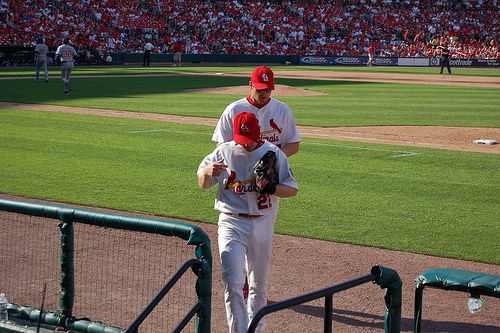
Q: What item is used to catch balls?
A: Glove.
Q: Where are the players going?
A: The dugout.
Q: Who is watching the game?
A: The spectator.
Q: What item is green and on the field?
A: Grass.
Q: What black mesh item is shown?
A: A net.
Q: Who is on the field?
A: Players.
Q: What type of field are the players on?
A: A baseball field.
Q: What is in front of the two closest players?
A: Railings of the dugout.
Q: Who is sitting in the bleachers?
A: The crowd.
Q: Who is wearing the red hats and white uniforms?
A: The baseball players.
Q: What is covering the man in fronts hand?
A: Catcher's mitt.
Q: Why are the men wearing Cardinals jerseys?
A: That's their team.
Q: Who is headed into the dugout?
A: The two players.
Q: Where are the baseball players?
A: On the field.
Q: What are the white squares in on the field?
A: Bases.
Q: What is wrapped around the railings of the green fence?
A: Padding.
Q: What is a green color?
A: Grass.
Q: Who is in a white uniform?
A: A baseball player.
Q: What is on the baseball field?
A: Grass.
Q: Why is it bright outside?
A: It's daytime.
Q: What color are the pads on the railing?
A: Green.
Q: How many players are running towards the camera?
A: Two.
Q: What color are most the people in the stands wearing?
A: Red.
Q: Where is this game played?
A: Baseball field.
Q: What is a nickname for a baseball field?
A: Diamond.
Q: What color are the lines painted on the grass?
A: White.